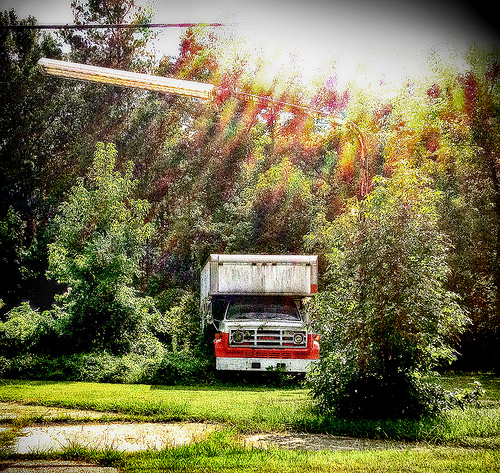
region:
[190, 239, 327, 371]
orange and white truck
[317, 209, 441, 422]
plant in the foreground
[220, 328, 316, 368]
orange on front of truck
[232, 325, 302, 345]
front grill of truck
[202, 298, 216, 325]
side view mirror of the truck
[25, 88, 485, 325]
trees behind orange and white truck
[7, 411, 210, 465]
cement pad on the left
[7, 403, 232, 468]
grass growing around cement pad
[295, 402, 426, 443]
grass growing in front of plant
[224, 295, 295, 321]
front windshield of truck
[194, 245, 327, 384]
a truck in the forest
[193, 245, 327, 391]
a white and red truck in the forest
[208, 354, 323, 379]
bumper of truck is white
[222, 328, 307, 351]
headlights in front of car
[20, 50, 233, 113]
a long light on a pole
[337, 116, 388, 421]
a pole on a field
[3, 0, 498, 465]
trees in the forest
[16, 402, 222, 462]
a puddle of water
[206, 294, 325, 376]
front of truck is white and red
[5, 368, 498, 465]
green grass in the forest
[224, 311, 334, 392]
big orange and white truck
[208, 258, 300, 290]
truck has cargo space in back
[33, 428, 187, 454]
big gap in green grass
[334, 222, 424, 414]
green leafy medium tree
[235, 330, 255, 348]
dirty headlamp on truck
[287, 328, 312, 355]
headlamp on white truck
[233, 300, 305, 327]
windshield of orange and white truck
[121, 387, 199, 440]
grass is bright green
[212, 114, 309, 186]
rainbow colors above trees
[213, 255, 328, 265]
red reflectors on truck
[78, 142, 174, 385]
This is a tree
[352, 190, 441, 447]
This is a tree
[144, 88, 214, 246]
This is a tree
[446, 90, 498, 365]
This is a tree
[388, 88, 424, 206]
This is a tree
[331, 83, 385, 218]
This is a tree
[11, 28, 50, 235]
This is a tree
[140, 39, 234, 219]
This is a tree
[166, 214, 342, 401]
This is a truck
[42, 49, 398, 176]
This is a pole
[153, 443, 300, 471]
The grass is short and green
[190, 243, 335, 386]
A moving truck in the trees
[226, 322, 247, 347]
The right side of head light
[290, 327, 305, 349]
The left side of the head light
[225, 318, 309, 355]
The grill to the truck is white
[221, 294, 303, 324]
The front windshield to the truck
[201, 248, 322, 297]
The cargo area of the truck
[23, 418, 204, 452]
A patch of the land is dirt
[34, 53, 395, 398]
A light in the park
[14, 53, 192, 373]
The trees are tall with green leaves